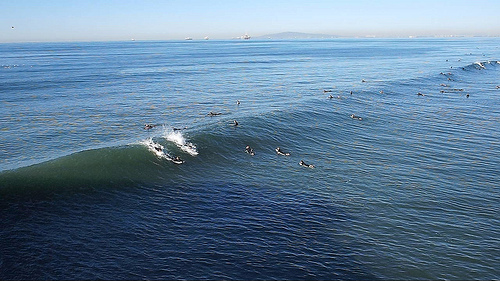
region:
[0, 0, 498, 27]
clear blue sky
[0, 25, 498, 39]
marine layer in distance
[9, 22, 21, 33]
item in the sky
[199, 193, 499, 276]
calm waves and ripples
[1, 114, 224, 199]
wave rolled in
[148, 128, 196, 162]
splashes from surfers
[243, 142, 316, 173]
three people laying on surf boards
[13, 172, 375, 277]
large shadow of cloud or seaweed underneath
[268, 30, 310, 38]
large hill in distance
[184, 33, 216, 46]
boats on water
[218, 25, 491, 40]
mountain in the distant horizon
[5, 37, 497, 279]
mostly calm blue ocean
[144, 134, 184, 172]
person riding wave on his/her belly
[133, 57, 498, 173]
individuals riding small wave together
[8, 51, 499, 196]
small wave coming into shore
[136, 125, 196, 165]
foamy white spray from individuals riding wave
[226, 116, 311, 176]
group of people coming from over the wave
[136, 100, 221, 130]
people swimming towards the wave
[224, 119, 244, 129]
person on the wave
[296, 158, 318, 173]
person finished riding the wave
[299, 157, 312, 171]
Person in the water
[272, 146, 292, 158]
Person in the water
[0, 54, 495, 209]
Large wave across the water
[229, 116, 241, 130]
Person in the water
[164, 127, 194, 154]
White splashing in the water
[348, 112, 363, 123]
Person in the water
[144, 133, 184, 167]
White splashing in the water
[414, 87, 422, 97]
Person in the water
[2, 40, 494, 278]
Large blue body of water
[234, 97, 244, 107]
Person in the water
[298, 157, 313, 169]
person in the water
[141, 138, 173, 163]
White splashes on wave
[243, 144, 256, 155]
person in the water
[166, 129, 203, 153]
White splashes on wave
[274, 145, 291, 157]
person in the water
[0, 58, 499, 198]
Large wave in water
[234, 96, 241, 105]
person in the water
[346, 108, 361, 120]
person in the water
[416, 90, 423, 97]
person in the water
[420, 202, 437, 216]
ripple in the water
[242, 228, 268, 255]
ripple in the water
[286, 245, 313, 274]
ripple in the water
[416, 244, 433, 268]
ripple in the water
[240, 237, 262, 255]
ripple in the water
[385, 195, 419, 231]
ripple in the water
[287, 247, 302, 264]
ripple in the water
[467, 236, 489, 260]
ripple in the water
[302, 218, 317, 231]
ripple in the water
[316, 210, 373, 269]
ripple in the water